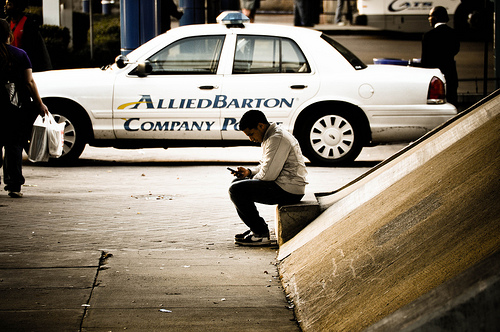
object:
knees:
[229, 182, 246, 201]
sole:
[236, 240, 271, 245]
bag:
[28, 113, 48, 163]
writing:
[116, 94, 294, 111]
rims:
[308, 112, 354, 159]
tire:
[295, 101, 367, 166]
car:
[20, 8, 462, 171]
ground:
[1, 145, 407, 330]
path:
[8, 168, 305, 330]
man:
[227, 110, 307, 245]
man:
[419, 5, 460, 107]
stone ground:
[1, 247, 102, 332]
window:
[229, 33, 310, 76]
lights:
[215, 10, 248, 26]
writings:
[123, 118, 284, 132]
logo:
[114, 93, 292, 131]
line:
[77, 248, 107, 332]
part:
[75, 247, 106, 329]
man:
[1, 18, 46, 195]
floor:
[4, 245, 294, 330]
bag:
[44, 110, 68, 160]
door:
[225, 32, 319, 142]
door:
[111, 33, 229, 143]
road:
[4, 143, 410, 164]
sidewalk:
[4, 167, 380, 330]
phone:
[226, 167, 245, 176]